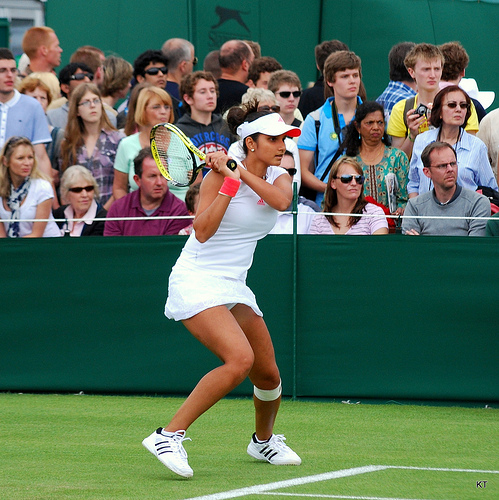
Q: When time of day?
A: Daytime.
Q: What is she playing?
A: Tennis.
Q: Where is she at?
A: Tennis court.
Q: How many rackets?
A: One.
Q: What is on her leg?
A: Brace.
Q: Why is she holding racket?
A: To hit ball.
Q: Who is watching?
A: Fans.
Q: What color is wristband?
A: Pink.